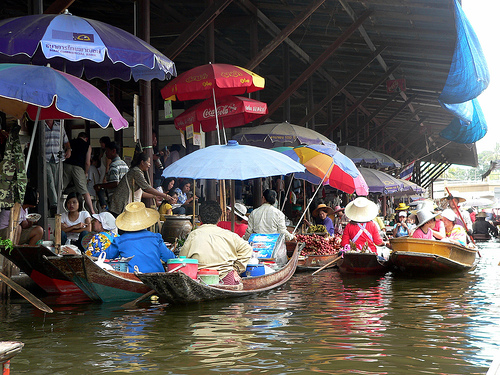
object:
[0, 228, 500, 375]
pond